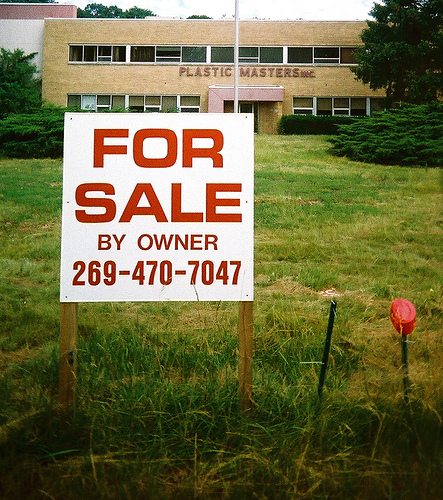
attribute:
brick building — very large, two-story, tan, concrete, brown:
[1, 2, 442, 136]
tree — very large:
[347, 0, 441, 109]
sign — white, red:
[60, 112, 254, 302]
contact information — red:
[72, 261, 241, 286]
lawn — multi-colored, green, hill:
[1, 133, 441, 499]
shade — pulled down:
[316, 98, 332, 110]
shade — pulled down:
[350, 98, 366, 110]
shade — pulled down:
[129, 96, 143, 108]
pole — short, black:
[318, 298, 337, 392]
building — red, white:
[0, 1, 77, 78]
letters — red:
[75, 129, 241, 250]